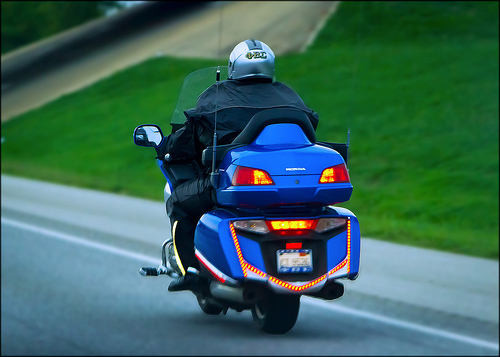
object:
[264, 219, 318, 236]
light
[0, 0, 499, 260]
grass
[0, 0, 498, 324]
hill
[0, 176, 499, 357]
ground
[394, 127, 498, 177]
wall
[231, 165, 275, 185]
light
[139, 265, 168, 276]
footrest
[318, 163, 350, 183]
light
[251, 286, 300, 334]
tire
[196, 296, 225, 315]
tire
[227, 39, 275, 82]
helmet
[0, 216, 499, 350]
line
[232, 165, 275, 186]
brake lights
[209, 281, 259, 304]
muffler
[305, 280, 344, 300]
muffler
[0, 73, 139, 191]
patch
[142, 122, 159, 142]
reflection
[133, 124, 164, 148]
mirror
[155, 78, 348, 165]
jacket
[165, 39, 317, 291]
man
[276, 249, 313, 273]
license plate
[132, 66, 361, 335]
motorcycle